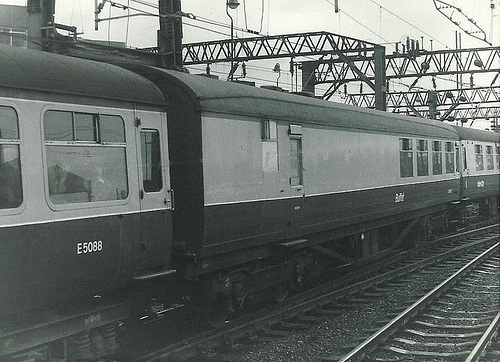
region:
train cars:
[10, 7, 499, 281]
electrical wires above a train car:
[11, 6, 498, 113]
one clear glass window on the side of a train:
[35, 83, 140, 237]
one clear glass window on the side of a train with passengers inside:
[25, 103, 145, 221]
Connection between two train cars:
[97, 48, 217, 333]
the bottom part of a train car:
[168, 191, 475, 312]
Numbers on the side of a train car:
[62, 225, 107, 262]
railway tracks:
[227, 226, 499, 354]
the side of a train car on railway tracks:
[202, 100, 459, 328]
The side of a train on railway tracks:
[36, 71, 498, 312]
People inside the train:
[31, 121, 108, 191]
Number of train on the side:
[71, 233, 116, 250]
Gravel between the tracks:
[289, 307, 341, 354]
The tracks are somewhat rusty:
[390, 283, 463, 359]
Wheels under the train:
[207, 231, 385, 341]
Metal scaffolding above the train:
[230, 46, 491, 184]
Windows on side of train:
[389, 126, 475, 189]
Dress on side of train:
[124, 106, 184, 276]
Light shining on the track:
[374, 285, 469, 357]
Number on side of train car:
[377, 190, 411, 205]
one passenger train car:
[161, 55, 462, 285]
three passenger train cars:
[58, 52, 497, 260]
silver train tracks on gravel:
[319, 253, 497, 358]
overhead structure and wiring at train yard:
[162, 7, 490, 139]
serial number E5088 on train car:
[72, 235, 107, 256]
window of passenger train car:
[34, 94, 139, 217]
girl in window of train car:
[37, 101, 142, 211]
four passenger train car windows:
[393, 130, 463, 177]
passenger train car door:
[130, 100, 179, 290]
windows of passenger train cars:
[31, 102, 498, 214]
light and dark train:
[18, 109, 485, 324]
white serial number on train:
[60, 228, 106, 256]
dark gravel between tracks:
[275, 272, 416, 355]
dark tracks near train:
[355, 292, 499, 354]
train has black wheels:
[199, 245, 333, 327]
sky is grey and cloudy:
[280, 3, 345, 74]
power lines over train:
[245, 22, 496, 131]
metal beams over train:
[167, 39, 401, 94]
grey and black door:
[125, 114, 187, 261]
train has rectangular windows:
[22, 110, 168, 213]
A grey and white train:
[22, 37, 484, 283]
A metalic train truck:
[169, 314, 364, 360]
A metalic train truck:
[369, 321, 499, 358]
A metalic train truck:
[329, 274, 488, 314]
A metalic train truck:
[427, 225, 486, 285]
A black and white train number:
[68, 241, 114, 263]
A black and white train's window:
[51, 104, 123, 199]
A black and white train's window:
[260, 121, 287, 169]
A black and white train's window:
[399, 123, 414, 173]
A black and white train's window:
[426, 132, 452, 183]